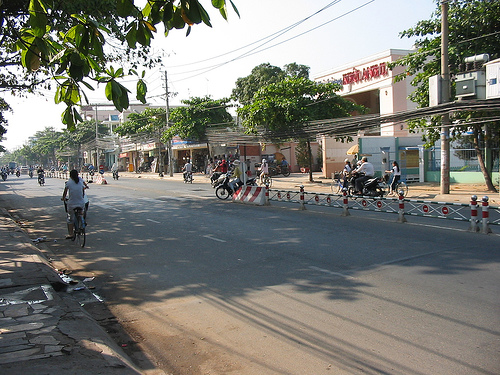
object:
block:
[232, 184, 267, 205]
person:
[60, 168, 90, 239]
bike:
[61, 194, 90, 248]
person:
[229, 159, 241, 192]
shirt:
[230, 167, 242, 179]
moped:
[215, 173, 259, 201]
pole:
[440, 1, 452, 194]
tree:
[231, 64, 309, 98]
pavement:
[0, 206, 115, 373]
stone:
[4, 331, 59, 362]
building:
[302, 49, 436, 180]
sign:
[342, 61, 389, 85]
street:
[0, 161, 497, 374]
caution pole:
[265, 181, 269, 205]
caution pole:
[299, 184, 306, 210]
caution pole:
[341, 187, 351, 216]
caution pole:
[396, 190, 408, 222]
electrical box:
[428, 74, 443, 107]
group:
[339, 154, 401, 195]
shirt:
[64, 178, 84, 205]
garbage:
[54, 268, 95, 292]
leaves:
[255, 75, 272, 84]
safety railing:
[265, 185, 496, 233]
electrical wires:
[206, 100, 499, 147]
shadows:
[26, 198, 60, 234]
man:
[181, 161, 194, 184]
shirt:
[183, 163, 192, 172]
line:
[147, 218, 161, 223]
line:
[113, 207, 122, 211]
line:
[203, 235, 228, 243]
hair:
[69, 169, 79, 184]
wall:
[321, 134, 358, 179]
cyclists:
[0, 166, 48, 187]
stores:
[78, 100, 207, 175]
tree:
[230, 62, 372, 182]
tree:
[391, 1, 500, 194]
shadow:
[148, 203, 289, 270]